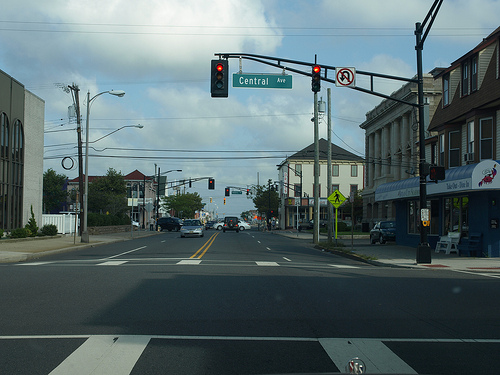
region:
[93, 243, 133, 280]
white lines are in road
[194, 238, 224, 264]
yellow lines are in road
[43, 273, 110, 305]
grey color road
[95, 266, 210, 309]
shadow are seen in road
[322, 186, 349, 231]
sign board is green in color.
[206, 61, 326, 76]
signal light is red in color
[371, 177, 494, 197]
shed is grey in color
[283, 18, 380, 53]
sky is blue in color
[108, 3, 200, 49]
clouds are white in color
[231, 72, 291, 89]
central ave is written in board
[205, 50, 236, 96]
The light is red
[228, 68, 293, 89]
The sign says central ave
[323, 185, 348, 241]
A pedestrian sign on the sidewalk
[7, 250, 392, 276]
A cross walk in the street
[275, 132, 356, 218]
A white house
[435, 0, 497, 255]
A business on the corner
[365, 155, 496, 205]
A awning over store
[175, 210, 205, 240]
The car in the distance is silver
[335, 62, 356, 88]
A no u-turn sign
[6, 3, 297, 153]
The sky is cloudy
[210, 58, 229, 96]
the traffic lights are red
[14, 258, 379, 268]
there is a cross walk at central avenue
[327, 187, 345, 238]
there is a fluorescent yellow crosswalk sign on the sidewalk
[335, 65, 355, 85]
a no u-turn sign is on the traffic light post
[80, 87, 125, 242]
the light posts are on bothe sides of the street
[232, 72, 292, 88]
the central avenue sign is green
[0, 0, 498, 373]
it is a sunny cloudy day in this town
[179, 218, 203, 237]
a silver car is approaching central avenue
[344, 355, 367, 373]
the logo of a buick vehicle is in the picture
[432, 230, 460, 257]
a white chair is on the sidewalk in front of a restaurant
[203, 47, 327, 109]
two red stop lights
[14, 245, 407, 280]
crosswalk painted white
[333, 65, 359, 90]
no u-turn sign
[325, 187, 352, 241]
a bright yellow sign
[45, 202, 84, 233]
a short white fence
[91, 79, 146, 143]
two street lights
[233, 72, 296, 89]
street sign showing Central Ave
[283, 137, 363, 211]
an old white building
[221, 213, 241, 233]
a jeep waiting at the light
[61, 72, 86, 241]
a utility pole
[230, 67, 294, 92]
street name Central Ave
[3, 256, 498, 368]
white walk lines on street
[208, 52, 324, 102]
red traffic lights suspended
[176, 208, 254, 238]
three cars on street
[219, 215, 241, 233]
red jeep on street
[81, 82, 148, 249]
two white lamp posts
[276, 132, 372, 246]
white brick building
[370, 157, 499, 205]
long white awning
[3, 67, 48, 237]
beige glass and brick building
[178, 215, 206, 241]
silver blue car on street